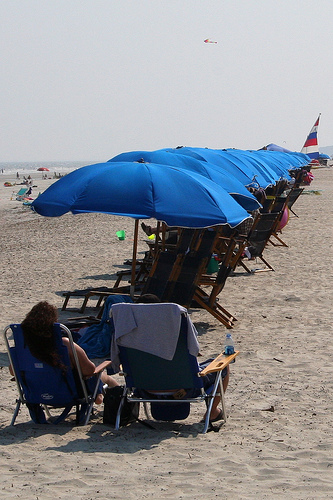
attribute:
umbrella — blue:
[153, 144, 260, 190]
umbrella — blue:
[219, 148, 277, 187]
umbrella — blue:
[247, 151, 292, 181]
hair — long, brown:
[18, 299, 70, 377]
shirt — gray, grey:
[107, 303, 202, 376]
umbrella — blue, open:
[22, 158, 255, 231]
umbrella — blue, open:
[105, 149, 263, 214]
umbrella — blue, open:
[154, 147, 258, 189]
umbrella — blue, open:
[212, 147, 281, 188]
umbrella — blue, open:
[243, 148, 295, 172]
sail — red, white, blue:
[299, 112, 325, 159]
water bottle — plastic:
[222, 332, 238, 364]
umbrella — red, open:
[35, 165, 50, 177]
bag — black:
[102, 384, 141, 428]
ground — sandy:
[0, 164, 333, 498]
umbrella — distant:
[35, 165, 51, 178]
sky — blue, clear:
[0, 1, 332, 163]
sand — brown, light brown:
[0, 159, 331, 498]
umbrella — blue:
[40, 156, 248, 300]